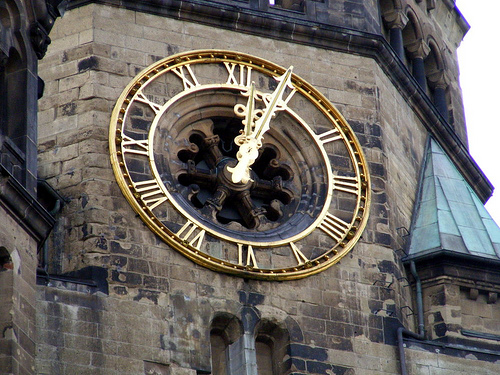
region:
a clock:
[105, 43, 370, 283]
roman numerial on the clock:
[232, 241, 257, 269]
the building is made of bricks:
[59, 25, 114, 101]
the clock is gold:
[107, 49, 372, 279]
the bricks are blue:
[425, 183, 474, 242]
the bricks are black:
[320, 14, 371, 45]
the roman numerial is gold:
[135, 178, 168, 209]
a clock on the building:
[99, 42, 386, 282]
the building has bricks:
[45, 297, 162, 360]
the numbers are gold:
[286, 240, 312, 263]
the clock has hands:
[111, 49, 371, 280]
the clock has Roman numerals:
[106, 48, 380, 278]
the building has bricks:
[0, 0, 499, 366]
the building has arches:
[382, 1, 464, 130]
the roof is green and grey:
[411, 138, 499, 265]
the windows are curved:
[206, 308, 295, 373]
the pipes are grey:
[393, 263, 430, 373]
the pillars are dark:
[393, 28, 458, 123]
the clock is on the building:
[1, 5, 493, 372]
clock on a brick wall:
[95, 35, 387, 285]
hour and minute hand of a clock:
[212, 56, 314, 187]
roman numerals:
[162, 26, 267, 98]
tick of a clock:
[226, 43, 320, 185]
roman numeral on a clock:
[125, 39, 367, 287]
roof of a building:
[397, 141, 498, 263]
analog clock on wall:
[92, 9, 402, 286]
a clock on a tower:
[72, 26, 387, 287]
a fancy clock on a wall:
[72, 39, 407, 300]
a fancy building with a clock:
[87, 28, 417, 308]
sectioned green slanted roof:
[403, 135, 498, 263]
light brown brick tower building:
[1, 0, 498, 373]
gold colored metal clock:
[106, 48, 368, 280]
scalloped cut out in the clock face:
[175, 113, 295, 231]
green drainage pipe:
[393, 260, 427, 374]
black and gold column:
[429, 66, 450, 120]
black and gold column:
[406, 35, 432, 93]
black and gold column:
[381, 8, 413, 71]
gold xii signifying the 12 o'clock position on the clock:
[223, 60, 253, 88]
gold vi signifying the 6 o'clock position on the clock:
[228, 240, 258, 266]